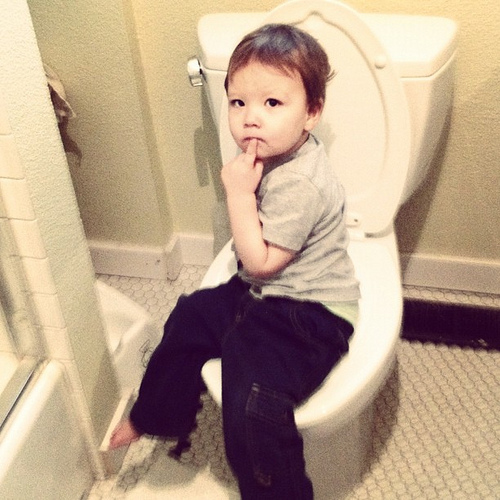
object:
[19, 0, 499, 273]
wall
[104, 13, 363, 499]
boy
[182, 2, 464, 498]
toilet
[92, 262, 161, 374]
potty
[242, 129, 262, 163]
finger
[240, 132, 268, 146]
mouth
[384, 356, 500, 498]
floor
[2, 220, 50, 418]
edge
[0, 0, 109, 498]
shower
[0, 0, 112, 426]
tile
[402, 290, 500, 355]
vent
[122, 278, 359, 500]
pants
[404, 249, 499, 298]
baseboard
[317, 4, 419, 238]
lid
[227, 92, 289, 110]
eyes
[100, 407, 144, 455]
foot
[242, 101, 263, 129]
nose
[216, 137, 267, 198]
hand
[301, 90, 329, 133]
ear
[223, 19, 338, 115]
hair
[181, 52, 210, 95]
handle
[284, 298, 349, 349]
pocket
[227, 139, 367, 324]
shirt